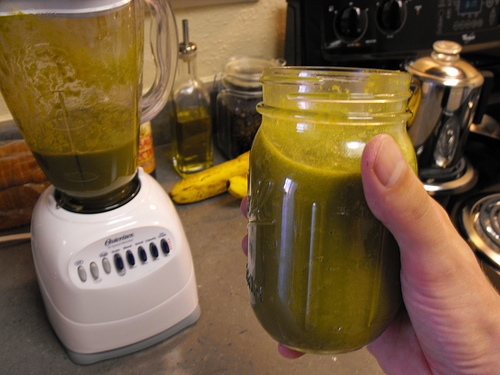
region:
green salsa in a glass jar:
[243, 63, 420, 355]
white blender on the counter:
[4, 0, 205, 365]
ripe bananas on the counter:
[166, 151, 248, 203]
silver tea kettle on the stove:
[406, 38, 483, 171]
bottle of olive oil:
[170, 16, 215, 171]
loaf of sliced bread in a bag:
[1, 135, 36, 228]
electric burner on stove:
[462, 188, 498, 260]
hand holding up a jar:
[236, 132, 494, 369]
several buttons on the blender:
[73, 238, 173, 283]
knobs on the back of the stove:
[328, 0, 412, 41]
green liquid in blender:
[20, 132, 159, 204]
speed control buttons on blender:
[70, 230, 187, 288]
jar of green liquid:
[242, 60, 412, 359]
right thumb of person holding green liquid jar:
[352, 125, 497, 372]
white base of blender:
[15, 163, 213, 371]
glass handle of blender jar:
[131, 0, 183, 133]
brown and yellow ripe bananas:
[164, 143, 259, 210]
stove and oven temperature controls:
[269, 0, 496, 75]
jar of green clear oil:
[157, 11, 220, 178]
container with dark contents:
[206, 46, 287, 157]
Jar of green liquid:
[241, 60, 416, 355]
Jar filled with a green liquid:
[245, 62, 416, 352]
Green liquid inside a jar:
[245, 62, 416, 355]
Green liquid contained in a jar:
[241, 61, 416, 352]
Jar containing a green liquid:
[245, 63, 417, 357]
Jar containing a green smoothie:
[244, 63, 419, 358]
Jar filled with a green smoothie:
[244, 62, 419, 354]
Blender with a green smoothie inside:
[0, 0, 202, 367]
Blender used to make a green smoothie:
[0, 0, 202, 364]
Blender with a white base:
[0, 0, 201, 366]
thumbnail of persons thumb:
[373, 139, 405, 186]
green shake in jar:
[276, 207, 346, 288]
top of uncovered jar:
[261, 61, 412, 108]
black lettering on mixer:
[103, 228, 140, 247]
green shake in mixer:
[63, 138, 132, 178]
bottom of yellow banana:
[172, 172, 207, 211]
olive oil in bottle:
[186, 118, 207, 162]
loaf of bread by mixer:
[5, 160, 32, 197]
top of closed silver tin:
[418, 48, 471, 78]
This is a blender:
[8, 8, 212, 365]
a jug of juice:
[165, 60, 225, 185]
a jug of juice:
[215, 40, 277, 185]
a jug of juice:
[6, 3, 183, 221]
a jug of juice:
[230, 54, 423, 364]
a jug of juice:
[209, 40, 279, 172]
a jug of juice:
[252, 42, 438, 373]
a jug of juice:
[10, 7, 153, 221]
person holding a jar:
[236, 54, 425, 364]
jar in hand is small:
[238, 49, 428, 356]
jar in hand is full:
[249, 59, 421, 356]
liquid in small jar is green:
[235, 103, 424, 358]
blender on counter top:
[1, 3, 209, 368]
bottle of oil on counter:
[169, 18, 221, 180]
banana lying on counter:
[170, 131, 257, 206]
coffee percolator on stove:
[377, 25, 498, 193]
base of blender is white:
[24, 168, 208, 369]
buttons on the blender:
[74, 245, 161, 270]